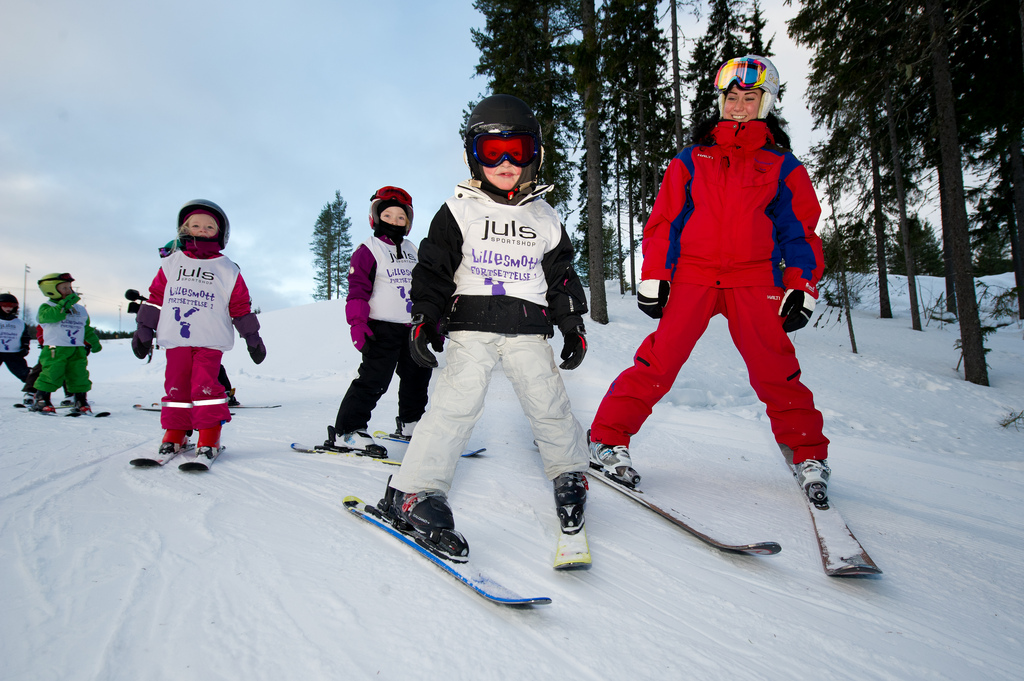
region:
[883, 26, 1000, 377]
green trees are in the background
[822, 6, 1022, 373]
Trees in the snow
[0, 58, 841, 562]
People are skiing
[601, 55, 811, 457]
The lady has on a red snow suit.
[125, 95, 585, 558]
The kids are enjoying themselves.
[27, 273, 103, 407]
The kid in the back has on a Green snowsuit.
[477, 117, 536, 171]
The kid in the front has on red goggles.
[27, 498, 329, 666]
The snow is white, and soft.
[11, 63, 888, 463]
They are ready to ski.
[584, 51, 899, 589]
The lady is teaching the kids how to ski.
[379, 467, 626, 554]
The kid in the front has on black ski shoes.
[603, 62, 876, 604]
Woman in red and blue snow suit.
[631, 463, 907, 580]
The woman's brown skis.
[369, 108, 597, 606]
A child in black and white ski suit.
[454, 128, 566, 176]
Blue rimmed red goggles.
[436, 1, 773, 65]
A patch of green trees.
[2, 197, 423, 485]
Four children skiing behind.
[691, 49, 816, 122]
A woman smiling at child.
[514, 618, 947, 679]
Grooves in the snow.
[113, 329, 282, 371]
A pair of black gloves.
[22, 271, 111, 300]
A pea green helmet.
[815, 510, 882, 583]
snow on woman's ski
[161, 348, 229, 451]
child wearing dark pink pants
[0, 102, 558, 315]
children are all wearing helmets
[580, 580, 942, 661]
lines on snow from previous passersby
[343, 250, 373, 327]
girl wearing purple jacket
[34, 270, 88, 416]
child wearing green outfit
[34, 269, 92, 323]
child looking to their left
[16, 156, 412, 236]
cloudy sky in the distance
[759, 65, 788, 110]
woman wearing white helmet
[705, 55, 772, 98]
woman's goggles on her head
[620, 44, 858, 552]
An adult on skis.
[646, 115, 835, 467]
She is wearing red.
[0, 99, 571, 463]
Five children on skis.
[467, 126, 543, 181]
Protective glasses with red and black.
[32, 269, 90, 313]
He is wearing a green helmet.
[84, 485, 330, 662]
White snow.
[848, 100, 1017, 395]
Pine trees lining the ski area.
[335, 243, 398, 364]
The coat has purple arms.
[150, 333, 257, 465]
The pants are pink.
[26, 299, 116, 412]
This outfit is green and white.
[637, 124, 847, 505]
person has on red ski suit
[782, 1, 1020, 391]
evergreen trees in the background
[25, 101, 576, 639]
several children skiing down a hill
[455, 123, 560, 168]
this child has red ski goggles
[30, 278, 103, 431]
small child in green and white ski suit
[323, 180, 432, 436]
child has purple white and black ski suit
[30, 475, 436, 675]
snow on the slopes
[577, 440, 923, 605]
people ski with the toes pointed inward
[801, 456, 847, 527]
the left foot of the adult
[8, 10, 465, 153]
the sky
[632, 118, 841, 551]
red with blue suit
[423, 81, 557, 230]
Kid is wearing red googles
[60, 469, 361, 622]
The snow is white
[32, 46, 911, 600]
It is winter season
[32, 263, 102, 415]
Kid's wearing green pants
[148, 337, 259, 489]
Young girl is wearing pink pants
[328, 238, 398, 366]
The sleeve is purple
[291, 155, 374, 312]
two pine trees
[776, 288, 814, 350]
The glove is black and white